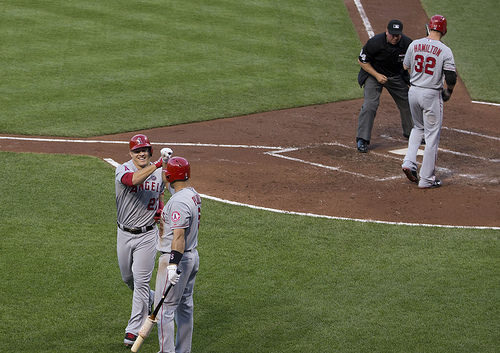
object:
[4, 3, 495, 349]
field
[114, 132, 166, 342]
player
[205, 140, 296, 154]
line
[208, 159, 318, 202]
dirt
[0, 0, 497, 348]
ground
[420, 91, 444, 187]
leg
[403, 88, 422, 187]
leg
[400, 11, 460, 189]
man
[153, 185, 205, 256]
jersey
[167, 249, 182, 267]
band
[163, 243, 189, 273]
wrist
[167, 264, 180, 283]
glove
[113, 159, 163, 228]
jersey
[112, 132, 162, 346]
man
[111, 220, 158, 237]
belt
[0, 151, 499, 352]
grass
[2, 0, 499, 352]
baseball field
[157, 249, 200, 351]
pants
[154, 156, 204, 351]
player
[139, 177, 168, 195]
logo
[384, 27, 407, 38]
hat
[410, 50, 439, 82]
number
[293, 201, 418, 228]
line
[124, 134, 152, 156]
helmet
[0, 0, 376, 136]
grass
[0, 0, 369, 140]
infield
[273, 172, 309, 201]
dirt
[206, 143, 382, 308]
field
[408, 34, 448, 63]
name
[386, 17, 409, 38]
cap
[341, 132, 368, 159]
shoe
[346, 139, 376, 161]
foot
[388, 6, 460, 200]
player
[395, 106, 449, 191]
legs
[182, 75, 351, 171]
ground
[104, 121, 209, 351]
players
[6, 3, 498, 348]
photo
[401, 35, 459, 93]
jersey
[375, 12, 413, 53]
head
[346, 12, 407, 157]
man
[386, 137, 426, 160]
plate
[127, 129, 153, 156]
helmet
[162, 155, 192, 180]
helmet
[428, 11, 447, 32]
helmet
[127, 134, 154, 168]
head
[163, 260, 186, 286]
hand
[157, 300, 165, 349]
stripe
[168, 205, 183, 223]
patch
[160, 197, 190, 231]
sleeve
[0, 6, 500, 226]
dirt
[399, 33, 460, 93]
shirt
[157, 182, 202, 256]
shirt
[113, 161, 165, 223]
shirt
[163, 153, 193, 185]
head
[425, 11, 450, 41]
head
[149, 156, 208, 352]
man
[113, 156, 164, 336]
uniform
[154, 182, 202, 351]
uniform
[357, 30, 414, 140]
uniform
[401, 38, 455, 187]
uniform